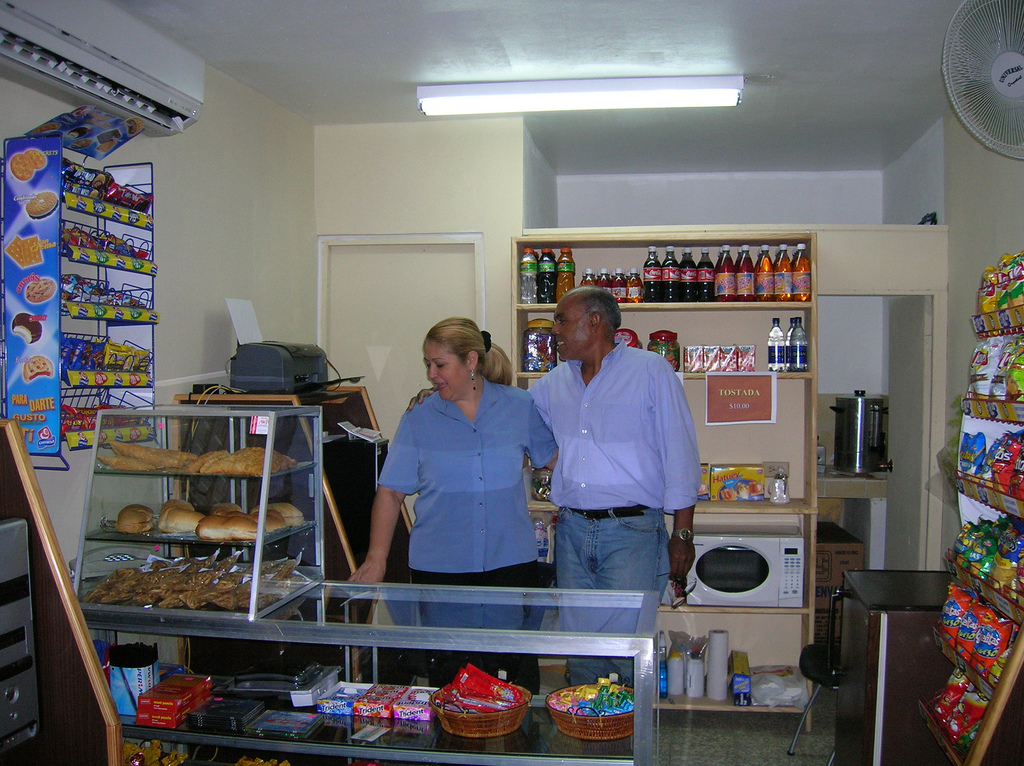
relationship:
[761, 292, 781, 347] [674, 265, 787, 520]
bottle of soda on shelf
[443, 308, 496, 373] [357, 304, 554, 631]
blonde colored hair of woman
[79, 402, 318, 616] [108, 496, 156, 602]
food in display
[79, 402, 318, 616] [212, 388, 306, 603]
food in display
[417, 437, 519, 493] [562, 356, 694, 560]
body of mans body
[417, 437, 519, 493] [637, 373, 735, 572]
body of mans body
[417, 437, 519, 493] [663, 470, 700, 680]
body of mans body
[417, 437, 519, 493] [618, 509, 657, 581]
body of mans body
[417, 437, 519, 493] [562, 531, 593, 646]
body of mans body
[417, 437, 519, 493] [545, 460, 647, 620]
body of mans body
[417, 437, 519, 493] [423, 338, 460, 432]
body of  womans body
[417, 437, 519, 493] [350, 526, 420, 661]
body of  womans body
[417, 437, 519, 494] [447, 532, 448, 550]
body has part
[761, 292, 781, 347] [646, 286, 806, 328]
bottle on shelf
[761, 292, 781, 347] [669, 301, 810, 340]
bottle on shelf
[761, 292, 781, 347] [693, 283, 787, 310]
bottle on shelf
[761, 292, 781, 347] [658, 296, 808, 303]
bottle on shelf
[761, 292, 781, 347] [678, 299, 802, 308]
bottle on shelf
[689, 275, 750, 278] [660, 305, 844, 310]
bottle on shelf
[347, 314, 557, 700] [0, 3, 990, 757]
man in store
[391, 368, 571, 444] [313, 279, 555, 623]
arm around woman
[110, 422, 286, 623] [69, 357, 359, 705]
food in case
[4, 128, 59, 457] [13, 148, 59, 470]
pictures of snacks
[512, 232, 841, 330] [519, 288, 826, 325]
drinks on shelf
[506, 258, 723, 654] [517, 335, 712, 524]
man in button down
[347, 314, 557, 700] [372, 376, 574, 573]
man in blouse